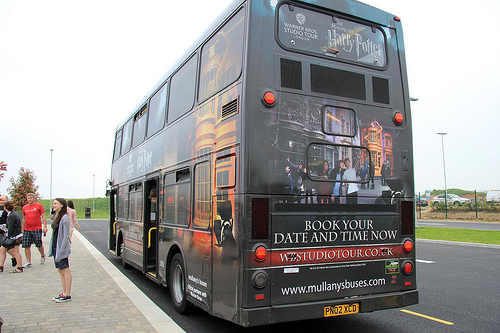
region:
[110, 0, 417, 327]
black double decker bus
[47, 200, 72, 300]
young woman is standing on the sidewalk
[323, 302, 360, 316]
yellow rectangle license plate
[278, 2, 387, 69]
movie advertisement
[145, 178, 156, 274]
rear passenger door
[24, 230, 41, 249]
black plaid shorts on the man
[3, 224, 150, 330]
brick side walk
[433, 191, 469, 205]
car parked in the parking lot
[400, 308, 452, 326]
yellow street line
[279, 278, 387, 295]
website advertisement on the bus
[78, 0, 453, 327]
a black double decker bus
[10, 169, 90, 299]
people standing at the sidewalk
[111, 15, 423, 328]
a tall black bus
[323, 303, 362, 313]
a yellow license plate on the bus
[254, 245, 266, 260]
a light on the bus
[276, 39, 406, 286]
writing on the bus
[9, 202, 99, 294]
people standing outside the bus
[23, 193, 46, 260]
a man wearing a red shirt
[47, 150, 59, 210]
a street light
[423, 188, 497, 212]
a fence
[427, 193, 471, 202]
a car behind the fence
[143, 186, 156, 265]
the door of the bus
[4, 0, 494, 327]
a group of people waiting beside a bus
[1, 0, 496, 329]
a bus parked on the street with a group of people on the sidewalk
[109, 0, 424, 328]
a black bus with pictures on it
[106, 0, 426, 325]
a bus with advertisements for the Harry Potter studio tour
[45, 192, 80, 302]
a girl standing on the sidewalk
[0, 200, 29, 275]
a girl wearing a grey sweater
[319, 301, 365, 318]
a yellow license plate with black writing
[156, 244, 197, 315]
the back left tire of a bus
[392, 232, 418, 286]
two red tail-lights on a bus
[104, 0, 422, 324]
Double deck bus on the side of the road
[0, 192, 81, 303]
People on the street near the bus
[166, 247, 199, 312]
Rear wheel of the double deck bus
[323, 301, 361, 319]
Plate number of the double deck bus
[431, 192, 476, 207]
Grey car in the back ground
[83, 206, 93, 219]
black dust bin on the side of the street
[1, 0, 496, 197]
Cloudy sky in the back ground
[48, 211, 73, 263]
grey sweater worn by person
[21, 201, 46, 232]
Red T-shirt worn by a man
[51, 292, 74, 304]
Black shoes worn by the girl